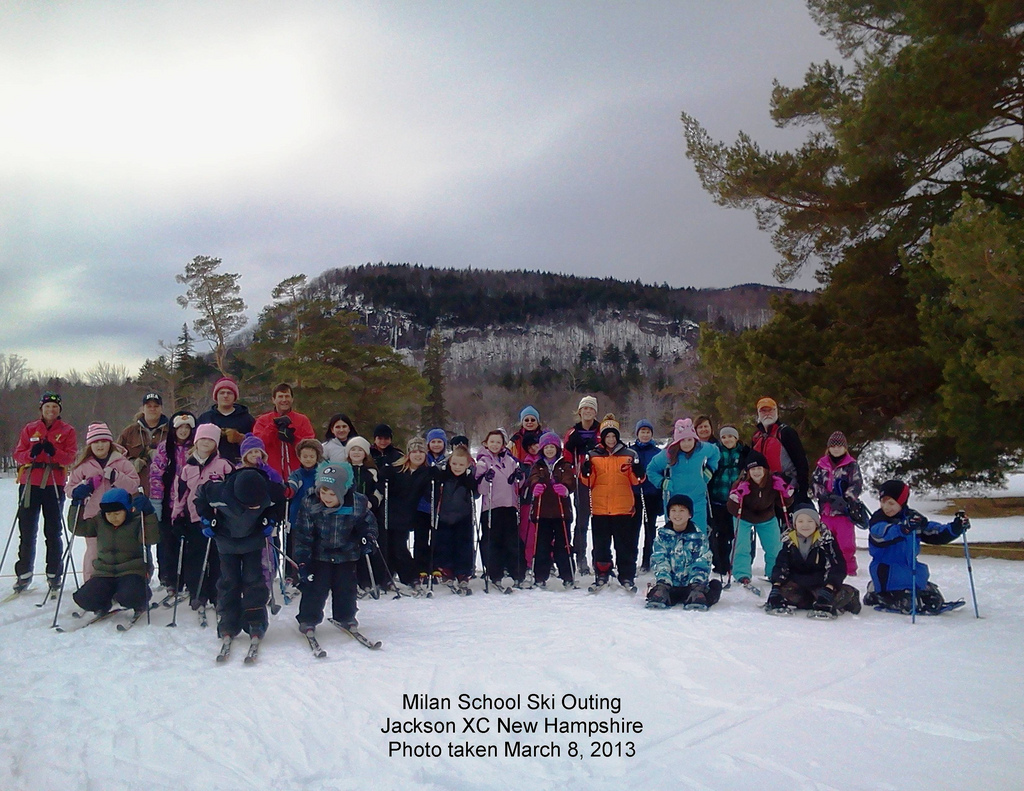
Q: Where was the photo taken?
A: At a ski resort.